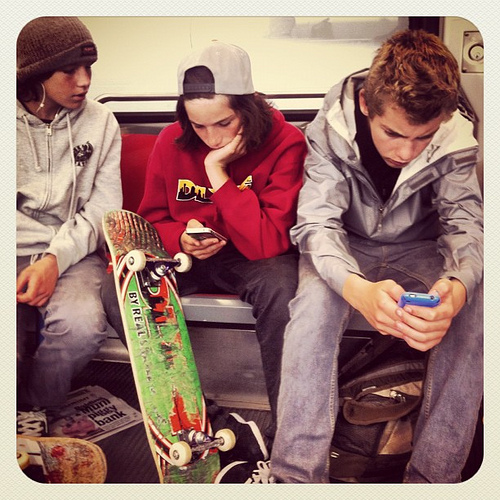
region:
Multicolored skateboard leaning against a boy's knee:
[99, 208, 236, 482]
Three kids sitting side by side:
[1, 12, 483, 482]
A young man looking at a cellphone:
[269, 27, 484, 482]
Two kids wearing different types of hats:
[17, 17, 275, 156]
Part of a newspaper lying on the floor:
[45, 382, 141, 443]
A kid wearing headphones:
[1, 15, 96, 119]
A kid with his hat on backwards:
[168, 35, 270, 159]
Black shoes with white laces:
[215, 410, 279, 482]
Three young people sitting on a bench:
[14, 14, 484, 481]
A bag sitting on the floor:
[330, 332, 425, 487]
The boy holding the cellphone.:
[354, 255, 446, 348]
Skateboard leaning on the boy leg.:
[96, 225, 228, 470]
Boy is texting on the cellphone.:
[164, 137, 242, 261]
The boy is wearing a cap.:
[165, 29, 269, 97]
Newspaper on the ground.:
[50, 391, 139, 448]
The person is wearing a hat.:
[23, 21, 113, 53]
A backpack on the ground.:
[326, 353, 408, 458]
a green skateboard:
[82, 194, 262, 498]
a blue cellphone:
[383, 276, 446, 340]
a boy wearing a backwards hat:
[148, 42, 294, 184]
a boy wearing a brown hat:
[18, 13, 108, 119]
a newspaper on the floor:
[36, 375, 166, 479]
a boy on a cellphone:
[130, 52, 288, 263]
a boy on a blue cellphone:
[312, 50, 472, 335]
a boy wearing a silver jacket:
[297, 43, 495, 309]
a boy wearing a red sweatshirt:
[131, 38, 301, 267]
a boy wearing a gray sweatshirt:
[12, 20, 122, 256]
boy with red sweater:
[151, 122, 284, 254]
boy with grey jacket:
[298, 103, 447, 295]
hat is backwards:
[163, 60, 242, 111]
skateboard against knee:
[168, 373, 290, 488]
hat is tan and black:
[168, 67, 287, 139]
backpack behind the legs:
[343, 333, 414, 459]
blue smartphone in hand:
[375, 275, 450, 339]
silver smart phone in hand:
[178, 204, 229, 267]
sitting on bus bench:
[153, 223, 447, 449]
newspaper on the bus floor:
[52, 374, 202, 466]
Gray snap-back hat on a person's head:
[175, 36, 265, 98]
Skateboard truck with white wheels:
[169, 428, 235, 467]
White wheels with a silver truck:
[124, 249, 192, 284]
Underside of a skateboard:
[103, 208, 236, 483]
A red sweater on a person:
[137, 108, 309, 260]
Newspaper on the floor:
[47, 382, 146, 445]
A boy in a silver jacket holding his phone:
[265, 27, 485, 482]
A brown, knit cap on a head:
[15, 15, 97, 78]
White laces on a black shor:
[16, 411, 47, 439]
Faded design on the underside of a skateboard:
[131, 283, 213, 435]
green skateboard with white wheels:
[99, 200, 234, 480]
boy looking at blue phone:
[270, 27, 481, 481]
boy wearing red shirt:
[104, 35, 303, 415]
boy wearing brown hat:
[15, 14, 128, 418]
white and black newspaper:
[37, 385, 144, 442]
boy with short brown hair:
[270, 29, 482, 481]